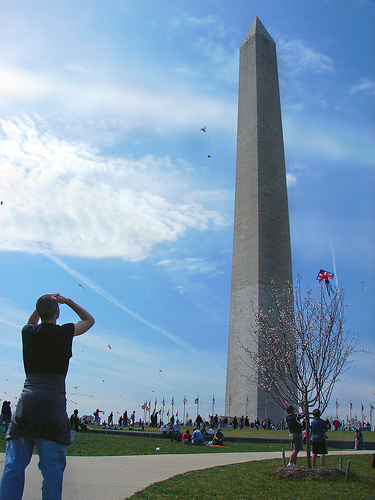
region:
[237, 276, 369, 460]
a tree with no leaves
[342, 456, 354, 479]
a short gray pole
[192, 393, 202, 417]
a tall flag pole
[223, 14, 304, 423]
a tall gray monument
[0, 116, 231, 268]
a large section of white clouds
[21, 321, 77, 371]
a man's black t-shirt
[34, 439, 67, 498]
the leg of a man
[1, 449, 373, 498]
a gray concrete walkway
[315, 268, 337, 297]
a colorful kite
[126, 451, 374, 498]
a section of green grass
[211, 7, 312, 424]
the Washington monument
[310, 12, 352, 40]
the clear blue sky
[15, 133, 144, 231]
the large cloud in the sky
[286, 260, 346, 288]
the kite in the sky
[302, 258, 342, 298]
the kite is red white and blue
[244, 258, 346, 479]
the tree with pink leaves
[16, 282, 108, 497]
the man looking up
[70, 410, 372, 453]
the large crowd on the grass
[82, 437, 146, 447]
the grass is green and trimmed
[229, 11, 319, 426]
the tall obelisk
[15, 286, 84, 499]
man covering eyes to look at monument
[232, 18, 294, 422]
large grey monument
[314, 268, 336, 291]
red and black kite in sky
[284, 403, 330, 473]
two people flying kite together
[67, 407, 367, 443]
crowd of people at base of monument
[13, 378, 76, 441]
black sweatshirt tied around waist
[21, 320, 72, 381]
black t-shirt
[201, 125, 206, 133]
blue kite high in sky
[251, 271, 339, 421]
budding tree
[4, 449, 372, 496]
concrete sidewalk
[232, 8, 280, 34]
top of tall statue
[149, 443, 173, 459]
white object on ground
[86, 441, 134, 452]
green grass on the side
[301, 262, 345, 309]
red and blue kite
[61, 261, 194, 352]
white streaks in the sky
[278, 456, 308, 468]
sneakers on woman's foot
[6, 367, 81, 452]
jacket around man's waist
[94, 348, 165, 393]
different kites in the sky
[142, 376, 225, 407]
flags flying on poles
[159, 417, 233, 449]
people sitting on the ground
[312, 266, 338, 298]
The red, blue and white kite.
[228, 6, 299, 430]
The cement monument.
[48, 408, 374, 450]
The grass area surrounding the monument.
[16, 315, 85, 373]
The guy in a black t-shirt with his hands near his face looking up.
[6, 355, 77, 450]
The gray sweater around the guy's waist.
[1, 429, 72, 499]
The blue jeans the guy is wearing that is looking up with his hands near his face.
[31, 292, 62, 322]
The head of the guy with his hands near his face looking up.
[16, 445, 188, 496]
The sidewalk area where the guy with hands next to his face is standing.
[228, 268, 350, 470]
The branches of the tree in the grass area.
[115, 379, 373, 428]
The flags surrounding the monument.